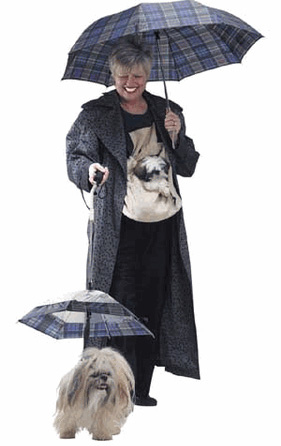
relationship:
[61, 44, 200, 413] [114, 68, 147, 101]
woman has face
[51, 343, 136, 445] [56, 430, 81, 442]
dog has foot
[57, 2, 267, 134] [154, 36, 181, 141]
umbrella has handle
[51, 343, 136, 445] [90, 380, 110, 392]
dog has mouth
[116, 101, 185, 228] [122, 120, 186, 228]
shirt has drawing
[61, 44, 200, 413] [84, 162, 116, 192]
woman has hand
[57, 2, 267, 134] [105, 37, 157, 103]
umbrella above head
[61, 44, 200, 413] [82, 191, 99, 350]
woman holding leash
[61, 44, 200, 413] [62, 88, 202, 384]
woman has coat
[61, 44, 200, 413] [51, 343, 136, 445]
woman has dog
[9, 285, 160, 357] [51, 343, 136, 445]
umbrella for dog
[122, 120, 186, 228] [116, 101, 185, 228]
drawing screened onto shirt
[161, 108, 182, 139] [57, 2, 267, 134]
hand holding umbrella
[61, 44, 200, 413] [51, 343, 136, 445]
woman with dog